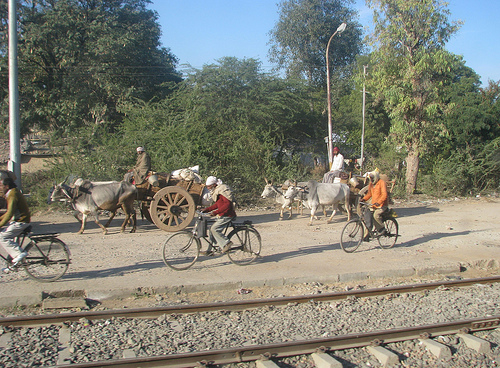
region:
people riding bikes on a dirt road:
[6, 189, 398, 261]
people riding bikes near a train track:
[9, 177, 407, 260]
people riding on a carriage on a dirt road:
[110, 124, 374, 165]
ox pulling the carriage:
[47, 177, 133, 232]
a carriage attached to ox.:
[58, 170, 177, 237]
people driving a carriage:
[117, 143, 364, 180]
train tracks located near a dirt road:
[99, 274, 496, 361]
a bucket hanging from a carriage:
[128, 169, 170, 194]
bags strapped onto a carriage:
[158, 157, 201, 179]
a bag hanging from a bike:
[189, 214, 214, 247]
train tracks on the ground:
[1, 265, 497, 365]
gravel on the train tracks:
[1, 269, 498, 365]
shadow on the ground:
[366, 230, 471, 245]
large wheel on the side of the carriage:
[146, 180, 203, 234]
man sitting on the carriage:
[126, 141, 161, 192]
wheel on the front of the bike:
[157, 228, 208, 273]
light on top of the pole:
[334, 18, 349, 36]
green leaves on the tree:
[266, 0, 376, 93]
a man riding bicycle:
[160, 176, 261, 271]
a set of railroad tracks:
[0, 274, 497, 365]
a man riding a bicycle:
[340, 167, 400, 253]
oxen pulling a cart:
[47, 163, 214, 231]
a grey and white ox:
[49, 180, 136, 236]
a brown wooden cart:
[130, 166, 205, 227]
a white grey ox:
[282, 173, 352, 221]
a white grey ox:
[259, 176, 306, 218]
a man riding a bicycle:
[0, 176, 72, 282]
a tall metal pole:
[4, 0, 22, 182]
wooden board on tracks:
[453, 328, 489, 353]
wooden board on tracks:
[418, 331, 455, 358]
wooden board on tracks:
[366, 346, 401, 366]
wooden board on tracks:
[310, 352, 341, 365]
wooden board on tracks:
[56, 329, 67, 364]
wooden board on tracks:
[113, 323, 140, 357]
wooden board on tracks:
[0, 327, 12, 366]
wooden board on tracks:
[262, 307, 298, 336]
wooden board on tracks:
[222, 316, 256, 346]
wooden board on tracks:
[163, 318, 190, 355]